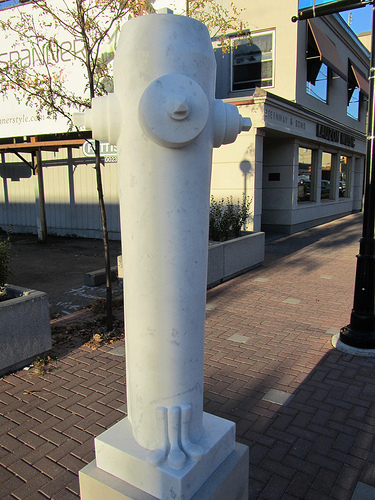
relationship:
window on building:
[347, 56, 369, 121] [0, 3, 374, 237]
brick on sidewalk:
[263, 387, 295, 410] [31, 234, 373, 499]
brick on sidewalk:
[259, 385, 297, 407] [19, 390, 90, 441]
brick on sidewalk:
[37, 412, 72, 446] [14, 381, 92, 452]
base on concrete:
[73, 407, 259, 495] [69, 5, 253, 497]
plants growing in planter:
[206, 190, 255, 240] [2, 264, 66, 381]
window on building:
[293, 143, 321, 208] [255, 15, 361, 237]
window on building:
[319, 147, 340, 205] [255, 15, 361, 237]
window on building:
[336, 154, 348, 201] [255, 15, 361, 237]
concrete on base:
[69, 5, 253, 497] [66, 393, 257, 498]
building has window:
[0, 3, 374, 237] [297, 145, 315, 204]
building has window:
[0, 3, 374, 237] [321, 151, 332, 200]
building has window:
[0, 3, 374, 237] [339, 155, 348, 197]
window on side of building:
[230, 32, 273, 88] [0, 3, 374, 237]